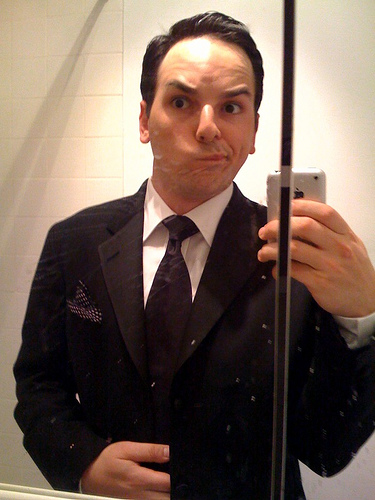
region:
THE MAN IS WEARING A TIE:
[135, 207, 213, 422]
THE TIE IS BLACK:
[132, 210, 205, 404]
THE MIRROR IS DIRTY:
[46, 222, 355, 498]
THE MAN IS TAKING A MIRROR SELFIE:
[9, 7, 373, 496]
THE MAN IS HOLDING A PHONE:
[250, 155, 331, 242]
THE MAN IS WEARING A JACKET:
[5, 175, 373, 499]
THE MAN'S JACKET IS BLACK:
[10, 174, 374, 499]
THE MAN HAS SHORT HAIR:
[134, 5, 272, 164]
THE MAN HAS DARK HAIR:
[134, 7, 265, 136]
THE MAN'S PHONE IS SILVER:
[254, 160, 326, 236]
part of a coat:
[203, 413, 212, 426]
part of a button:
[181, 480, 184, 496]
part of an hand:
[130, 472, 141, 493]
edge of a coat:
[86, 455, 90, 460]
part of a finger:
[127, 444, 142, 463]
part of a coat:
[134, 284, 153, 292]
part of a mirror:
[250, 377, 273, 418]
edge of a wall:
[1, 415, 22, 459]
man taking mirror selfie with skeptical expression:
[26, 5, 355, 483]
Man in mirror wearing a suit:
[34, 16, 327, 485]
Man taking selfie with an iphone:
[121, 30, 372, 355]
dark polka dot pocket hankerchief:
[64, 276, 109, 326]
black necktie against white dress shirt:
[146, 216, 194, 361]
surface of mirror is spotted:
[21, 225, 355, 469]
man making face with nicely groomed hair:
[123, 14, 268, 199]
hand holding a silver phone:
[252, 155, 373, 360]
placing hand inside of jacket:
[58, 426, 197, 497]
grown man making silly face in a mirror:
[20, 10, 361, 445]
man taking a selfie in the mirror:
[15, 8, 370, 499]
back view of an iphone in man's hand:
[266, 172, 322, 226]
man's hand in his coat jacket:
[80, 432, 175, 495]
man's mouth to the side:
[194, 150, 236, 166]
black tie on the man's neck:
[136, 213, 198, 386]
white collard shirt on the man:
[136, 178, 235, 298]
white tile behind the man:
[1, 3, 123, 487]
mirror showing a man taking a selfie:
[7, 1, 373, 498]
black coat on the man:
[15, 181, 372, 498]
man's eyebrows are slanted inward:
[165, 74, 256, 100]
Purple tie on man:
[146, 251, 192, 442]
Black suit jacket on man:
[16, 178, 373, 498]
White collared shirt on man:
[135, 173, 248, 318]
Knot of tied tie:
[160, 227, 187, 261]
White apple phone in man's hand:
[259, 164, 336, 279]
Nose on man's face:
[184, 97, 224, 145]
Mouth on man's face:
[181, 147, 236, 170]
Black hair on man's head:
[137, 9, 263, 120]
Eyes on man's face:
[160, 92, 253, 123]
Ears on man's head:
[132, 96, 271, 162]